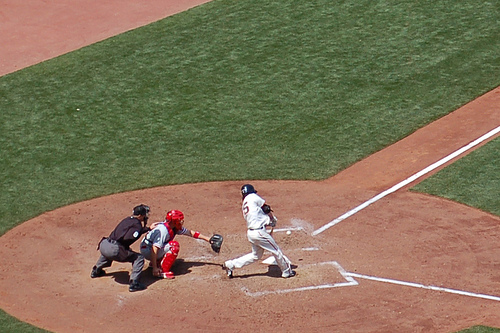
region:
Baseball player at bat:
[238, 176, 290, 311]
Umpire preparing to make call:
[91, 198, 153, 288]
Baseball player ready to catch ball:
[137, 205, 224, 294]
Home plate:
[236, 223, 306, 283]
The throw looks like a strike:
[275, 220, 345, 247]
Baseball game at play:
[80, 165, 381, 301]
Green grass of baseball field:
[143, 35, 338, 175]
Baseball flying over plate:
[285, 227, 295, 235]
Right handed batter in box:
[200, 185, 327, 315]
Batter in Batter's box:
[215, 252, 370, 302]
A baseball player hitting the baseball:
[220, 171, 305, 282]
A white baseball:
[284, 227, 294, 238]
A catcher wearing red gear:
[137, 200, 230, 291]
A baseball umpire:
[91, 201, 152, 295]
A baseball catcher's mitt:
[206, 231, 230, 255]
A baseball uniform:
[225, 180, 296, 280]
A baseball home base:
[256, 248, 298, 272]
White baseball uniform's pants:
[224, 223, 298, 285]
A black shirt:
[104, 213, 146, 248]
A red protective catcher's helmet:
[160, 205, 187, 234]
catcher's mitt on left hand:
[207, 232, 224, 253]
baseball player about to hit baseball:
[226, 183, 296, 278]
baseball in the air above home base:
[285, 227, 290, 237]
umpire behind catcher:
[92, 203, 223, 290]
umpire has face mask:
[131, 203, 150, 225]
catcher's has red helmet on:
[166, 209, 185, 224]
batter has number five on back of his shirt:
[223, 185, 290, 277]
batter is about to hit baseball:
[223, 184, 295, 280]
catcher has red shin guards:
[161, 239, 176, 279]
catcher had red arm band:
[192, 230, 199, 236]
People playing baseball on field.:
[63, 167, 368, 316]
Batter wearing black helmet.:
[236, 178, 265, 199]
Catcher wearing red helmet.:
[159, 203, 189, 233]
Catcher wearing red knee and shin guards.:
[163, 239, 180, 274]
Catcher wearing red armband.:
[191, 224, 203, 243]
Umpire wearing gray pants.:
[77, 232, 149, 298]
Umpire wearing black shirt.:
[108, 215, 147, 246]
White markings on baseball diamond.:
[288, 192, 493, 310]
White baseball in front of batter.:
[279, 223, 303, 240]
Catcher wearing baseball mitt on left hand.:
[208, 230, 226, 258]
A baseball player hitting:
[219, 175, 304, 283]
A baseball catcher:
[160, 209, 220, 274]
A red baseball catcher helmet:
[155, 204, 190, 221]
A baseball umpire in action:
[92, 194, 146, 271]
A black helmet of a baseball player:
[227, 180, 262, 200]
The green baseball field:
[60, 107, 245, 159]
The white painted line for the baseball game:
[366, 171, 391, 216]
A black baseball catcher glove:
[206, 228, 227, 261]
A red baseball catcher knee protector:
[164, 242, 179, 277]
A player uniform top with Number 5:
[237, 198, 264, 231]